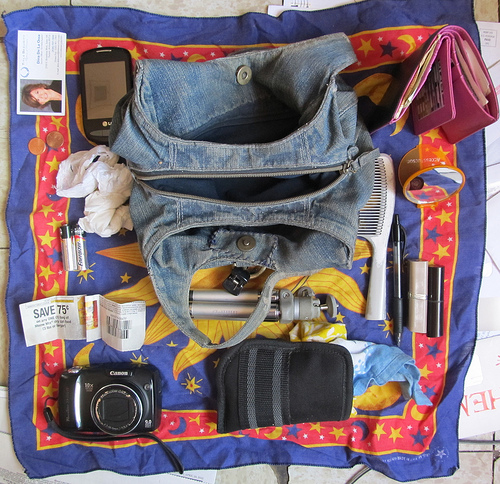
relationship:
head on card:
[21, 82, 51, 110] [17, 29, 68, 119]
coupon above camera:
[17, 292, 146, 353] [59, 363, 159, 437]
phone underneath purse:
[78, 45, 134, 150] [107, 32, 381, 350]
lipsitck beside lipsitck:
[410, 260, 428, 332] [408, 261, 429, 333]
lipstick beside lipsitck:
[429, 266, 442, 339] [408, 261, 429, 333]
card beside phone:
[17, 29, 68, 119] [78, 45, 134, 150]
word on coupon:
[33, 304, 54, 318] [17, 292, 146, 353]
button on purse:
[234, 66, 253, 87] [107, 32, 381, 350]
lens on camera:
[88, 382, 147, 437] [59, 363, 159, 437]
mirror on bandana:
[396, 144, 465, 209] [186, 422, 460, 481]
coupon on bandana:
[17, 292, 146, 353] [186, 422, 460, 481]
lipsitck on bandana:
[408, 261, 429, 333] [186, 422, 460, 481]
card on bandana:
[17, 29, 68, 119] [186, 422, 460, 481]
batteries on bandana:
[61, 225, 91, 273] [186, 422, 460, 481]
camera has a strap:
[59, 363, 159, 437] [45, 404, 182, 476]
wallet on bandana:
[370, 27, 500, 146] [186, 422, 460, 481]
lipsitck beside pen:
[408, 261, 429, 333] [391, 212, 405, 350]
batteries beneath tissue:
[61, 225, 91, 273] [56, 143, 137, 238]